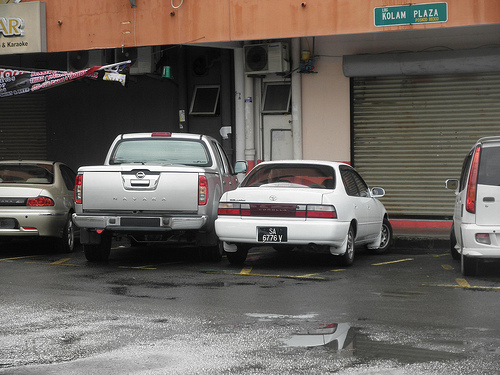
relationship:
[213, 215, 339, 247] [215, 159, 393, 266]
back bumper on car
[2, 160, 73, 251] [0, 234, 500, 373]
sedan in parking lot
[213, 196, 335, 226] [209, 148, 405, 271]
tail light on car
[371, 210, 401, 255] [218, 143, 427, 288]
tire on car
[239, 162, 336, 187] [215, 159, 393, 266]
windshield on car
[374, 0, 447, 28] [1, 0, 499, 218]
sign on building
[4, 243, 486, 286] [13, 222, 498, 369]
lines on pavement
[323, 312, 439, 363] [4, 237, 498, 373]
puddle in street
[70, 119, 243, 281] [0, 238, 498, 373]
truck in lot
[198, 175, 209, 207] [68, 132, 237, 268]
light on back of truck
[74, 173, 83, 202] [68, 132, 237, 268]
light on back of truck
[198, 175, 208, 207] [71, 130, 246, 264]
light on back of truck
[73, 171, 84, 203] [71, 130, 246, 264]
light on back of truck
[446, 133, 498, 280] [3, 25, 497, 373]
suv parked in parking lot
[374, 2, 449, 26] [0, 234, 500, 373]
sign above parking lot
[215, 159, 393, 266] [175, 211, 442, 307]
car parked in spot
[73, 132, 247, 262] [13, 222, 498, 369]
truck parked on pavement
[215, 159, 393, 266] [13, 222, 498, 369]
car parked on pavement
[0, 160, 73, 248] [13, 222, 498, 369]
sedan parked on pavement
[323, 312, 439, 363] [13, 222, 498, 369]
puddle on pavement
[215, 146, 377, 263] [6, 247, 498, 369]
car parked in lot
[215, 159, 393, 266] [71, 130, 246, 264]
car parked next to truck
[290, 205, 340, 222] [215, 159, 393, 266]
light on a car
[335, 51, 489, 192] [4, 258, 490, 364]
door facing parking lot